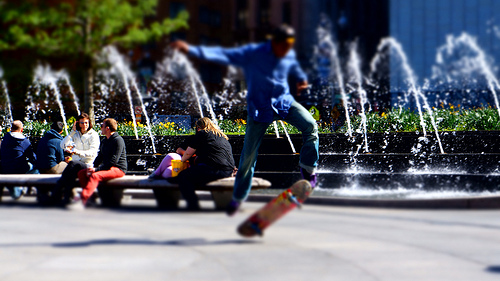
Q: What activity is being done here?
A: Skateboarding.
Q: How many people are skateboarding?
A: One.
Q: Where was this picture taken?
A: A park.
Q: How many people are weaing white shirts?
A: One.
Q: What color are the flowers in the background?
A: Yellow.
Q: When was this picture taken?
A: Daytime.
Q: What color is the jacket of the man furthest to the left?
A: Blue.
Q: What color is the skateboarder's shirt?
A: Blue.